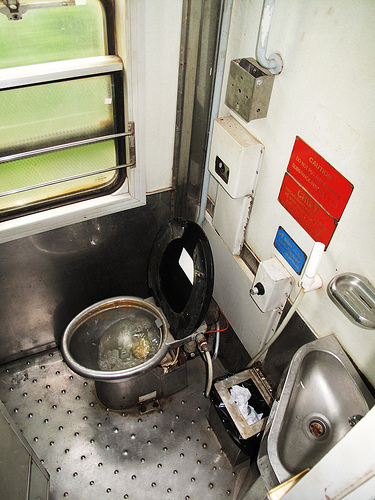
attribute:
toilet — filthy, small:
[57, 215, 211, 410]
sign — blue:
[271, 226, 307, 276]